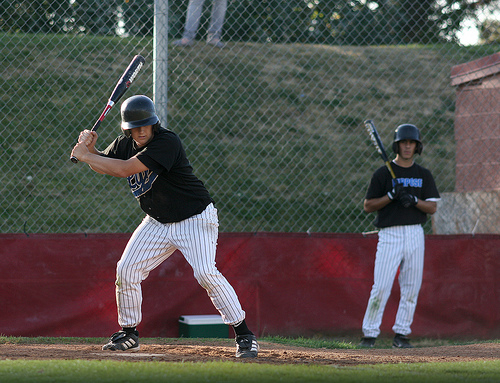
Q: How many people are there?
A: Two.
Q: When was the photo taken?
A: During the day.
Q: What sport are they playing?
A: Baseball.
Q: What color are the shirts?
A: Black.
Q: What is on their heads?
A: Helmets.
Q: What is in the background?
A: A fence.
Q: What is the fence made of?
A: Metal.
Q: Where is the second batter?
A: By the fence.